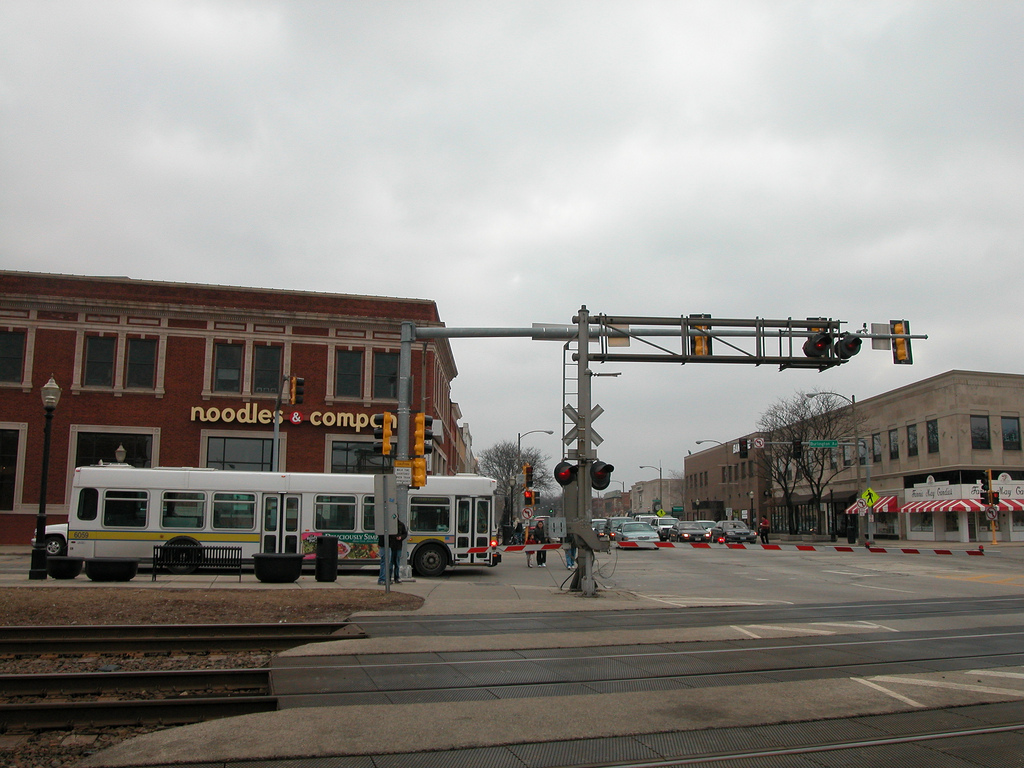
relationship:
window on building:
[72, 328, 127, 396] [3, 170, 546, 657]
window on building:
[223, 293, 303, 440] [22, 215, 524, 650]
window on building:
[335, 336, 375, 458] [3, 207, 438, 568]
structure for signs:
[545, 297, 950, 658] [586, 274, 973, 426]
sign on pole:
[551, 408, 653, 475] [543, 300, 608, 584]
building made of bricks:
[11, 239, 506, 605] [76, 298, 258, 471]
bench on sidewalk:
[132, 529, 258, 601] [85, 527, 330, 627]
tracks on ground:
[42, 626, 192, 730] [31, 576, 310, 747]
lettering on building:
[187, 397, 380, 432] [14, 258, 453, 576]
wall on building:
[3, 271, 436, 570] [14, 258, 453, 576]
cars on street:
[612, 507, 755, 546] [426, 544, 1023, 765]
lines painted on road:
[854, 669, 1023, 709] [504, 552, 1023, 766]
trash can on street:
[294, 519, 355, 602] [71, 508, 672, 638]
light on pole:
[36, 376, 63, 407] [30, 402, 59, 524]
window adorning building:
[210, 335, 245, 394] [9, 262, 450, 544]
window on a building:
[327, 346, 369, 418] [9, 262, 450, 544]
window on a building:
[361, 336, 409, 419] [14, 258, 453, 576]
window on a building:
[121, 327, 163, 403] [9, 262, 450, 544]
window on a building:
[114, 318, 163, 403] [9, 262, 450, 544]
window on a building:
[201, 430, 284, 472] [9, 262, 450, 544]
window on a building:
[325, 431, 395, 466] [9, 262, 450, 544]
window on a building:
[11, 318, 35, 392] [9, 262, 450, 544]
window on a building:
[966, 411, 992, 455] [673, 368, 993, 546]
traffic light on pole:
[411, 411, 425, 463] [383, 316, 423, 554]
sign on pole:
[508, 498, 535, 531] [523, 463, 536, 535]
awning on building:
[843, 480, 993, 519] [673, 368, 993, 546]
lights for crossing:
[551, 458, 614, 498] [605, 538, 994, 578]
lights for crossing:
[802, 331, 863, 355] [616, 536, 993, 593]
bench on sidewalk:
[143, 538, 245, 584] [16, 571, 505, 593]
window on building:
[72, 329, 163, 396] [9, 262, 450, 544]